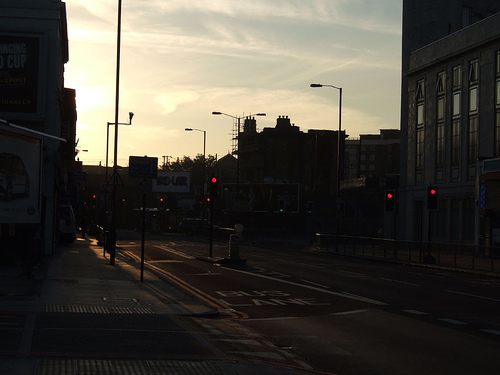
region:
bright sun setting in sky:
[61, 67, 111, 119]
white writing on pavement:
[211, 275, 310, 316]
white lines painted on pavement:
[332, 289, 401, 326]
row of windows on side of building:
[399, 75, 499, 163]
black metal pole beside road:
[104, 5, 129, 273]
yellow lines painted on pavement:
[159, 273, 199, 296]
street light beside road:
[301, 78, 358, 105]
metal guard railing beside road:
[308, 225, 485, 271]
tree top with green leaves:
[170, 152, 204, 175]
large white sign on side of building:
[149, 165, 198, 195]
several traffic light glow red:
[86, 174, 437, 207]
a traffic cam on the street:
[101, 103, 136, 268]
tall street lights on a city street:
[178, 78, 353, 138]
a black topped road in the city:
[115, 229, 495, 372]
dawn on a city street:
[73, 113, 499, 354]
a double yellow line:
[117, 245, 241, 333]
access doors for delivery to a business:
[6, 303, 235, 362]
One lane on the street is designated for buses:
[99, 228, 494, 370]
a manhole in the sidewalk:
[101, 291, 137, 309]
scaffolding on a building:
[229, 114, 246, 154]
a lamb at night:
[196, 165, 236, 194]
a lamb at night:
[273, 200, 290, 218]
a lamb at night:
[84, 187, 114, 210]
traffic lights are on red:
[377, 174, 445, 215]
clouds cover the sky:
[119, 27, 294, 90]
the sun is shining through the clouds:
[74, 32, 114, 152]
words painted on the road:
[209, 282, 336, 322]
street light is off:
[299, 72, 349, 209]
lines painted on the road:
[141, 258, 216, 312]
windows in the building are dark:
[406, 74, 487, 161]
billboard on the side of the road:
[146, 165, 191, 195]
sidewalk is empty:
[61, 227, 106, 282]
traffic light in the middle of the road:
[202, 157, 247, 279]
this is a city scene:
[23, 24, 477, 370]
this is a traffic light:
[191, 162, 233, 200]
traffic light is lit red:
[200, 155, 225, 205]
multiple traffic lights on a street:
[77, 153, 459, 279]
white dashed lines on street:
[385, 287, 485, 349]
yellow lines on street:
[145, 242, 245, 347]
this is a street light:
[303, 67, 363, 244]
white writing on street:
[188, 259, 328, 324]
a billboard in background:
[131, 152, 211, 203]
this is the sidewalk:
[52, 233, 150, 304]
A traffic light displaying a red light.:
[202, 175, 222, 206]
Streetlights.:
[180, 64, 351, 244]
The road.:
[104, 208, 498, 371]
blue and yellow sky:
[86, 46, 158, 96]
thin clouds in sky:
[143, 11, 220, 76]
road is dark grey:
[174, 251, 279, 316]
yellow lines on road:
[145, 269, 225, 292]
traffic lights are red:
[99, 149, 238, 227]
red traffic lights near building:
[361, 172, 478, 226]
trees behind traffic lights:
[140, 140, 242, 183]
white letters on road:
[205, 256, 320, 328]